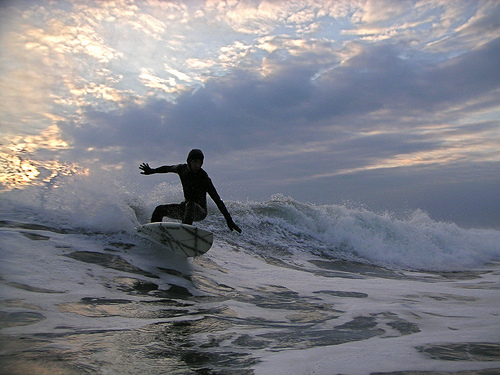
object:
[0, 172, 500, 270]
wave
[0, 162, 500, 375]
water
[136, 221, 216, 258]
surfboard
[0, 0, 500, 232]
clouds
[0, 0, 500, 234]
sky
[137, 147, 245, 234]
man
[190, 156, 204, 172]
face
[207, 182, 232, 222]
arms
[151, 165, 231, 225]
wetsuit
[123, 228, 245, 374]
reflection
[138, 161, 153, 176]
right hand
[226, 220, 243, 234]
left hand